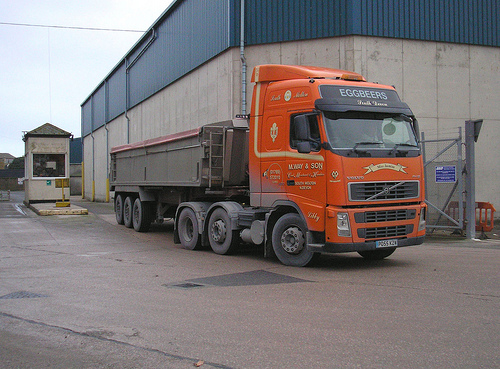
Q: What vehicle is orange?
A: The truck.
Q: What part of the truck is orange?
A: The cab.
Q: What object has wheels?
A: The truck.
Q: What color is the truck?
A: Orange.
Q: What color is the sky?
A: Blue.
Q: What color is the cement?
A: Grey.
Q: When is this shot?
A: Daytime.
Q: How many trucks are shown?
A: 1.